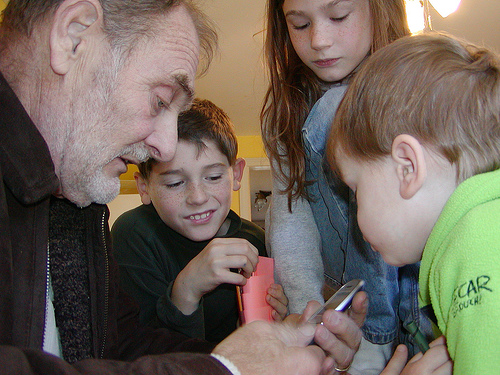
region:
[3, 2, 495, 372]
three children and a man looking at a cell phone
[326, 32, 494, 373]
boy with brown hair and a light green shirt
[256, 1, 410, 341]
girl with long brown hair and a gray sweatshirt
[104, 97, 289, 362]
boy with brown hair and a black shirt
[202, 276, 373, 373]
man's hands holding a cell phone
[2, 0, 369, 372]
man with brown and gray hair and a brown jacket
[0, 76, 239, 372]
white shirt under a brown jacket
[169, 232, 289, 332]
two hands holding pink paper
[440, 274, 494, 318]
dark green lettering on a sleeve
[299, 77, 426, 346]
part of a blue denim jacket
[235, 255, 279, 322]
red paper in the boys hands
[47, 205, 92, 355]
fur lighted coat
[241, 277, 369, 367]
cell phone in the man's hands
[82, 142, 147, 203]
beard and mustache is gray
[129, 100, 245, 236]
little boy is smiling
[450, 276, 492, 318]
logo on the jacket arm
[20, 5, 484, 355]
group of people looking at the phone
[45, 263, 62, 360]
white shirt under the jacket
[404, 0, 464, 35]
the ceiling light is on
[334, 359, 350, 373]
a wedding band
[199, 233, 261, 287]
Hand of young boy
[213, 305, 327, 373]
Hand of talking man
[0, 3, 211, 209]
Head of talking man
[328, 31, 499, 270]
Head of listening child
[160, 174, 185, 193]
Eye of young boy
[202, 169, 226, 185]
Eye of young boy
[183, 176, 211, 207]
Nose of young boy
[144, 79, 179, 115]
Eye of talking man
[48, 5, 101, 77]
Ear of talking man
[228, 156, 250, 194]
Ear of young boy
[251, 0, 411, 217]
Girl has long brown hair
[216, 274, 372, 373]
Cell phone in two hands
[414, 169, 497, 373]
The shirt is green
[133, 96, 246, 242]
The boy is smiling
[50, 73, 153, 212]
White facial hair on man's face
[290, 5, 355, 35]
Two eyes are closed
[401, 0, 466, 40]
A light is turned on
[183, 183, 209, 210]
Nose on boy's face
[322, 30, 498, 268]
Boy has light brown hair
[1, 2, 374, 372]
A man looking at a cell phone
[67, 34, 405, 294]
the family is looking at a phone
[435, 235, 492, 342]
the man is wearing a green sweater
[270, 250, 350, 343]
the phone is silver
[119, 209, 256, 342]
the boy is smiling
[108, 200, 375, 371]
the boy has a black sweater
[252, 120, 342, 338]
the girl has a gray sweater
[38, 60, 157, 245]
the man has a gray beard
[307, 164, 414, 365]
the girl is wearing jeans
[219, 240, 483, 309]
the man is holding a phone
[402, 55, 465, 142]
the boy has red hair